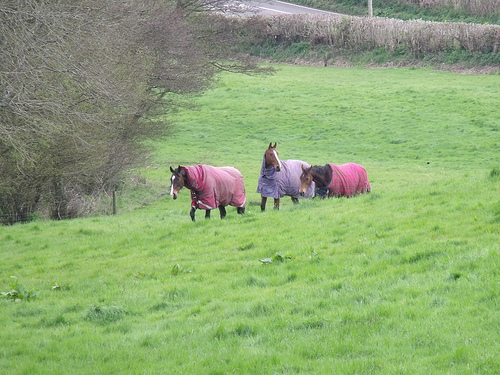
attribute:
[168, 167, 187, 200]
head — white, brown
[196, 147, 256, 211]
blanket — red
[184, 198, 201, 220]
leg — brown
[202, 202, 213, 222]
leg — brown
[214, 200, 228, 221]
leg — brown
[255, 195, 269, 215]
leg — brown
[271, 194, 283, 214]
leg — brown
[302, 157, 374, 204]
horse — covered, brown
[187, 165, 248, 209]
blanket — red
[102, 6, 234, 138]
tree — brown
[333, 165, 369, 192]
cover — red, checkered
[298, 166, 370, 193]
horse — all brown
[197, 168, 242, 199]
fabric — pink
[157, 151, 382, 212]
horses — three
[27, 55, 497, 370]
field — green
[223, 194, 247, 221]
leg — brown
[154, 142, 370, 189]
horses — three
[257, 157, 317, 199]
blanket — purple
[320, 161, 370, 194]
blanket — red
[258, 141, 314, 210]
horse — brown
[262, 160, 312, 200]
covering — purple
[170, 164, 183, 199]
head — white, brown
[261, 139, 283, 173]
head — brown, white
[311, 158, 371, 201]
fabric — pink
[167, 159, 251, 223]
horse — first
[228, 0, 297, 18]
line — white